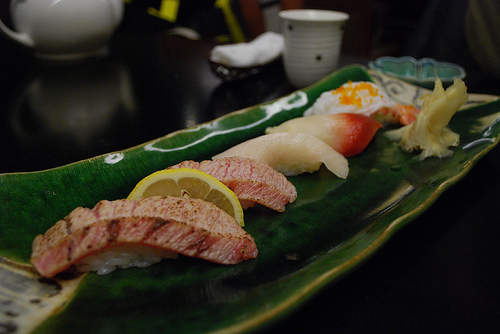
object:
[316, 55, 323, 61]
circle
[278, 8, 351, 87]
cup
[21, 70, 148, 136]
surface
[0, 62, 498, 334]
plate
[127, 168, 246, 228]
slice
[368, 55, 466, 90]
bowl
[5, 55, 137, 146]
reflection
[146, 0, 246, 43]
object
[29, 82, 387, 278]
food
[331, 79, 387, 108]
topping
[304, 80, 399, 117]
creme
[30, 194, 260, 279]
beef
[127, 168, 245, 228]
orange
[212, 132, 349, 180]
pineapple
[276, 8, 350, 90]
cut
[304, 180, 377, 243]
veggie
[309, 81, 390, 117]
cheese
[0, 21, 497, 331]
table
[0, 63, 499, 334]
dish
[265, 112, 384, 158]
shrimp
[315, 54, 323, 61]
hole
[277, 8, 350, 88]
glass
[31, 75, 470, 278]
sushi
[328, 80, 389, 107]
sprinkle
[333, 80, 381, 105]
condiment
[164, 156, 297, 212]
meat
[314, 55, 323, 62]
dot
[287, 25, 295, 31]
dot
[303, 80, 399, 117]
sour cream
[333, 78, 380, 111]
zest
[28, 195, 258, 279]
protein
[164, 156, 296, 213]
protein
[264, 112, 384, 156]
protein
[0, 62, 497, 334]
prate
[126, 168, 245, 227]
lemon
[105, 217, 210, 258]
marks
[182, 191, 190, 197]
seed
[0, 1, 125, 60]
pitcher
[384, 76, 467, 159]
ginger